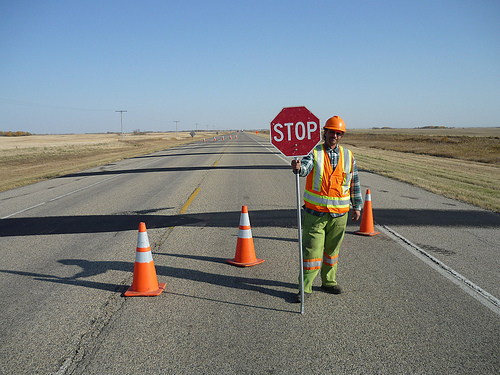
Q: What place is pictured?
A: It is a road.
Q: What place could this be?
A: It is a road.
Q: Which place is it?
A: It is a road.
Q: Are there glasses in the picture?
A: No, there are no glasses.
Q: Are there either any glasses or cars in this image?
A: No, there are no glasses or cars.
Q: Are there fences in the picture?
A: No, there are no fences.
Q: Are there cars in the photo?
A: No, there are no cars.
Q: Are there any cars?
A: No, there are no cars.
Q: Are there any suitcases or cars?
A: No, there are no cars or suitcases.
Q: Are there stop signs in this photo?
A: Yes, there is a stop sign.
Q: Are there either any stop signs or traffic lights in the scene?
A: Yes, there is a stop sign.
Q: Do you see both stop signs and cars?
A: No, there is a stop sign but no cars.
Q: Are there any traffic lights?
A: No, there are no traffic lights.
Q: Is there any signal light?
A: No, there are no traffic lights.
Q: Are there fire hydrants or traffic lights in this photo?
A: No, there are no traffic lights or fire hydrants.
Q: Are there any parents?
A: No, there are no parents.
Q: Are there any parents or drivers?
A: No, there are no parents or drivers.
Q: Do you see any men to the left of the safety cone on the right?
A: Yes, there is a man to the left of the traffic cone.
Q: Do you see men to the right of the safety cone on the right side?
A: No, the man is to the left of the cone.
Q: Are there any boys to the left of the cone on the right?
A: No, there is a man to the left of the cone.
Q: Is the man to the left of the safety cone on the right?
A: Yes, the man is to the left of the traffic cone.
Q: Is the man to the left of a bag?
A: No, the man is to the left of the traffic cone.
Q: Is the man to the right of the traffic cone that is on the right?
A: No, the man is to the left of the traffic cone.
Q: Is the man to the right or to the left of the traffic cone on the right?
A: The man is to the left of the cone.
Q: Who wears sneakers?
A: The man wears sneakers.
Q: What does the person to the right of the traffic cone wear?
A: The man wears sneakers.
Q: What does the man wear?
A: The man wears sneakers.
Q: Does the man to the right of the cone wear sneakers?
A: Yes, the man wears sneakers.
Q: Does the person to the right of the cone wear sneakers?
A: Yes, the man wears sneakers.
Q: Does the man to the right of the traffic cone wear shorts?
A: No, the man wears sneakers.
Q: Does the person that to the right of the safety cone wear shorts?
A: No, the man wears sneakers.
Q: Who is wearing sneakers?
A: The man is wearing sneakers.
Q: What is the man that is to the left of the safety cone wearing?
A: The man is wearing sneakers.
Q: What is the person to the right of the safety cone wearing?
A: The man is wearing sneakers.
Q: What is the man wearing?
A: The man is wearing sneakers.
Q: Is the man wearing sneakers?
A: Yes, the man is wearing sneakers.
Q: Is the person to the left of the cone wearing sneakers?
A: Yes, the man is wearing sneakers.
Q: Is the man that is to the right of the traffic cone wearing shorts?
A: No, the man is wearing sneakers.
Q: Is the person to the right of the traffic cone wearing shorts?
A: No, the man is wearing sneakers.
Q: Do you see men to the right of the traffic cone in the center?
A: Yes, there is a man to the right of the cone.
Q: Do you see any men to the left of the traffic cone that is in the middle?
A: No, the man is to the right of the traffic cone.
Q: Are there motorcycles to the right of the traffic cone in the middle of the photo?
A: No, there is a man to the right of the cone.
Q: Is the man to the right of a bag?
A: No, the man is to the right of a cone.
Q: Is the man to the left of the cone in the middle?
A: No, the man is to the right of the cone.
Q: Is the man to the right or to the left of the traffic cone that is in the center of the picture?
A: The man is to the right of the safety cone.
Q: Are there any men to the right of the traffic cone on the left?
A: Yes, there is a man to the right of the traffic cone.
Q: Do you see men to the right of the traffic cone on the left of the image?
A: Yes, there is a man to the right of the traffic cone.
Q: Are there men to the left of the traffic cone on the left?
A: No, the man is to the right of the traffic cone.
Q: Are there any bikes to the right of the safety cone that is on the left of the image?
A: No, there is a man to the right of the traffic cone.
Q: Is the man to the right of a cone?
A: Yes, the man is to the right of a cone.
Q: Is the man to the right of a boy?
A: No, the man is to the right of a cone.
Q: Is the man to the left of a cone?
A: No, the man is to the right of a cone.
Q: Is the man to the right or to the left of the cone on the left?
A: The man is to the right of the cone.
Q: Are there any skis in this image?
A: No, there are no skis.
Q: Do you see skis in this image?
A: No, there are no skis.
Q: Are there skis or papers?
A: No, there are no skis or papers.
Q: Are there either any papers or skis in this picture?
A: No, there are no skis or papers.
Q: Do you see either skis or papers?
A: No, there are no skis or papers.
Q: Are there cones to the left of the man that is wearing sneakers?
A: Yes, there is a cone to the left of the man.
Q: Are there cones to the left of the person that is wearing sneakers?
A: Yes, there is a cone to the left of the man.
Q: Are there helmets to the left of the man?
A: No, there is a cone to the left of the man.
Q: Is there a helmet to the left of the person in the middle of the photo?
A: No, there is a cone to the left of the man.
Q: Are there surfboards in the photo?
A: No, there are no surfboards.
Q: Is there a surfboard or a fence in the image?
A: No, there are no surfboards or fences.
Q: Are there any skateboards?
A: No, there are no skateboards.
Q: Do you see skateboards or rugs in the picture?
A: No, there are no skateboards or rugs.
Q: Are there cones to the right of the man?
A: Yes, there is a cone to the right of the man.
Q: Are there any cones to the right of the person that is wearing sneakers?
A: Yes, there is a cone to the right of the man.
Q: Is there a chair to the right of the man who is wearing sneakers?
A: No, there is a cone to the right of the man.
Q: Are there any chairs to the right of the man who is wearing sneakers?
A: No, there is a cone to the right of the man.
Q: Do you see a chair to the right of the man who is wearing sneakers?
A: No, there is a cone to the right of the man.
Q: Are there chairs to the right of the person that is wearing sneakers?
A: No, there is a cone to the right of the man.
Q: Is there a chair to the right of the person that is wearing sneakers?
A: No, there is a cone to the right of the man.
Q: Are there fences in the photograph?
A: No, there are no fences.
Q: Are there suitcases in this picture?
A: No, there are no suitcases.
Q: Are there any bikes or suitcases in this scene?
A: No, there are no suitcases or bikes.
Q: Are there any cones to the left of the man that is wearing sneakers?
A: Yes, there is a cone to the left of the man.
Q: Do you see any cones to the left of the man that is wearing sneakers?
A: Yes, there is a cone to the left of the man.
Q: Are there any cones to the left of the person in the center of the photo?
A: Yes, there is a cone to the left of the man.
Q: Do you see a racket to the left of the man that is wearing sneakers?
A: No, there is a cone to the left of the man.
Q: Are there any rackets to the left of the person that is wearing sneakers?
A: No, there is a cone to the left of the man.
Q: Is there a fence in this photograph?
A: No, there are no fences.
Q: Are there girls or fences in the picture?
A: No, there are no fences or girls.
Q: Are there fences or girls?
A: No, there are no fences or girls.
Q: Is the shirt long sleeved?
A: Yes, the shirt is long sleeved.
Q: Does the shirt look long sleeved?
A: Yes, the shirt is long sleeved.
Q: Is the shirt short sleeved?
A: No, the shirt is long sleeved.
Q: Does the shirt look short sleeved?
A: No, the shirt is long sleeved.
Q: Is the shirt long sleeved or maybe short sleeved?
A: The shirt is long sleeved.